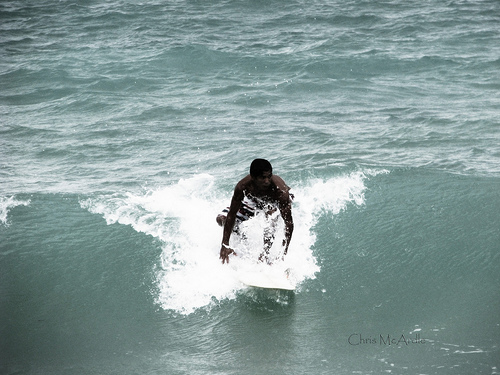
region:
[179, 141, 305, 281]
man on surf board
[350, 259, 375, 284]
white and gray ocean waves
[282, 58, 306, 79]
white and gray ocean waves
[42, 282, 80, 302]
white and gray ocean waves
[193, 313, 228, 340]
white and gray ocean waves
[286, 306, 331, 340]
white and gray ocean waves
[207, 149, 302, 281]
man standing on board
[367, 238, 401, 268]
white and gray ocean waves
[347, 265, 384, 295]
white and gray ocean waves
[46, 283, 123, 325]
white and gray ocean waves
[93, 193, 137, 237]
white and gray ocean waves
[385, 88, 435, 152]
white and gray ocean waves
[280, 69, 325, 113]
white and gray ocean waves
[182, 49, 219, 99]
white and gray ocean waves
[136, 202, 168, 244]
white and gray ocean waves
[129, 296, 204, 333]
white and gray ocean waves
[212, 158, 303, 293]
Man on surf board.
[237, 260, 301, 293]
White surfboard in water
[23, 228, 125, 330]
Blue ocean water on left side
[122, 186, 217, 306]
White wave in ocean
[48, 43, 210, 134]
Waves on the water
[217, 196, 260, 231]
Striped bathing suit trunks.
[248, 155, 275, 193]
Dark hair on man's head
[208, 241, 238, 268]
A hand in water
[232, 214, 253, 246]
Man's leg in the water.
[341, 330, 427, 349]
Photographers name listed on right side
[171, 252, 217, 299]
a white wave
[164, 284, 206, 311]
the water is white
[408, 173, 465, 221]
the water is green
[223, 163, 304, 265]
a person surfing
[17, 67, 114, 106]
small waves in the water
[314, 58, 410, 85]
a small wave in the water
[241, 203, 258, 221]
man is wearing shorts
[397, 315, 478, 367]
bubbles in the water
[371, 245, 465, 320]
the water in the ocean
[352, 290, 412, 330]
the ocean water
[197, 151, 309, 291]
man on surfboard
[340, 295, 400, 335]
white and gray ocean waves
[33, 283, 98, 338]
white and gray ocean waves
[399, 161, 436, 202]
white and gray ocean waves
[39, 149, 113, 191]
white and gray ocean waves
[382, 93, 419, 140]
white and gray ocean waves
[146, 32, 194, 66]
white and gray ocean waves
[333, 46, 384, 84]
white and gray ocean waves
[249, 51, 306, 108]
white and gray ocean waves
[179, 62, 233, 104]
white and gray ocean waves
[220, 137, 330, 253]
man is on water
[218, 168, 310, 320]
man is on board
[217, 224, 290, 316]
man on white surfboard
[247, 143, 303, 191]
man has dark hair